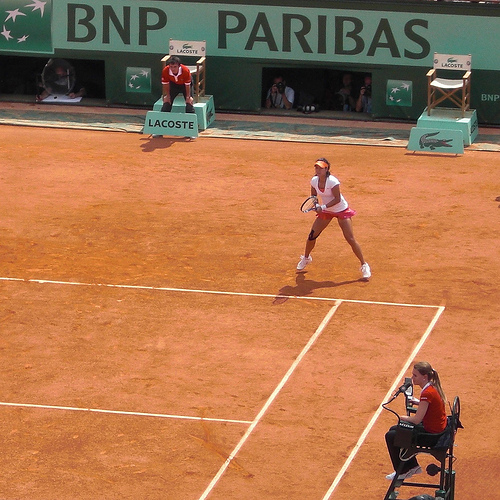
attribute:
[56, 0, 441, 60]
bnp paribas —  BNP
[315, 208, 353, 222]
skirt — red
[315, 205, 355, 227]
shorts — red 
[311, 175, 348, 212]
shirt — white 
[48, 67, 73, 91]
tv camera —  TV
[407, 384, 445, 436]
shirt — red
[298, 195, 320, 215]
racket —  tennis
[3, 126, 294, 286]
floor — orange dirt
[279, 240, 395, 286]
shoes — white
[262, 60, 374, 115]
dugout — media and photographer dugout, right dugout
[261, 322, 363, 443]
sideline — singles' sideline, tennis court's sideline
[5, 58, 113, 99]
media dugout — media and photographer dugout, left dugout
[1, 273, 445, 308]
baseline — tennis court's baseline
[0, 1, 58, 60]
logo — BNP Paribas logo, largest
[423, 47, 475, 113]
chair — White 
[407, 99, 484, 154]
block — green 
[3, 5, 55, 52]
logo — green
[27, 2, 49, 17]
star — white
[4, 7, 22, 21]
star — white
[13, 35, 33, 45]
star — white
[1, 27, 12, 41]
star — white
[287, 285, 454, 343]
lines — white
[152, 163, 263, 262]
ground — dirt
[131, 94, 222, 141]
chair — blue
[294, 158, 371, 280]
tennis player — female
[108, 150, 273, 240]
red dirt —  red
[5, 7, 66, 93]
corner — upper-left coner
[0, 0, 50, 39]
stars — four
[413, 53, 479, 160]
chair — blue